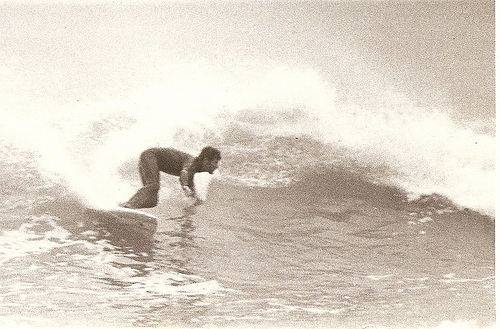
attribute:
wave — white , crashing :
[240, 73, 495, 233]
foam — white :
[0, 213, 232, 325]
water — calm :
[1, 203, 496, 326]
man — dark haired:
[119, 121, 230, 204]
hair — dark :
[198, 144, 220, 160]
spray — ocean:
[12, 2, 497, 175]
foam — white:
[0, 70, 495, 215]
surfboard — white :
[86, 204, 161, 251]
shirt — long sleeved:
[159, 146, 199, 191]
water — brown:
[3, 2, 499, 326]